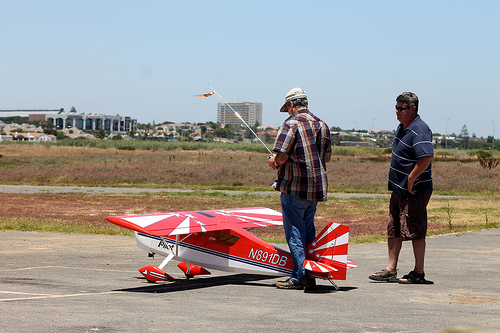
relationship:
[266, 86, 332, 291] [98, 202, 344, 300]
man with airplane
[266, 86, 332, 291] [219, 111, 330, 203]
man with control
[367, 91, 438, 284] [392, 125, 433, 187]
man wearing shirt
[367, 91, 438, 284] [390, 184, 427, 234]
man wearing pants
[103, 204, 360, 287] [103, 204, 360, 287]
airplane model airplane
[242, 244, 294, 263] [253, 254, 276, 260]
letters says n891db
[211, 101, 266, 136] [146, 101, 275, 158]
building seen in distance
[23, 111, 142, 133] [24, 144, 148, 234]
building seen in distance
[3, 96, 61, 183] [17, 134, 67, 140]
building with roof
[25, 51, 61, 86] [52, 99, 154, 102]
clouds in sky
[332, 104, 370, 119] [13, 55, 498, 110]
clouds in sky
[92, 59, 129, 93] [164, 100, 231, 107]
clouds in sky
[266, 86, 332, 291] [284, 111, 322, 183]
man wearing shirt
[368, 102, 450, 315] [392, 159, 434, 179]
man wearing shirt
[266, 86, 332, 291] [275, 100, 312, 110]
man has on a cap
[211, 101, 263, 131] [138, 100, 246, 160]
building in background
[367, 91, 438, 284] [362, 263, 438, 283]
man wearing shoes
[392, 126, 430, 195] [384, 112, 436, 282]
shirt of man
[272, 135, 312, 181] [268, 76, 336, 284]
shirt of man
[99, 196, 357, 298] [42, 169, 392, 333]
airplane on ground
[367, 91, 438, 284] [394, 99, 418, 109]
man has hair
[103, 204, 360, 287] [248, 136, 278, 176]
airplane  remote control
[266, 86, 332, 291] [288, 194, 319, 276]
man wearing jeans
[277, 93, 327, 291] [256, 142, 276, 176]
man holding remote control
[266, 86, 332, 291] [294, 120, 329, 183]
man wearing shirt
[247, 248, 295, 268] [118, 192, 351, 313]
numbers on plane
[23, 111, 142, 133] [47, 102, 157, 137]
building in back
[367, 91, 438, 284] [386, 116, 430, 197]
man wearing shirt